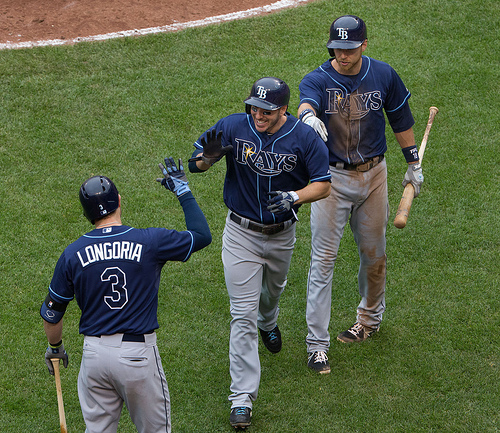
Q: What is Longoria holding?
A: Bat.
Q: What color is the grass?
A: Green.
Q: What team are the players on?
A: Rays.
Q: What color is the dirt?
A: Brown.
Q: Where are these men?
A: On field.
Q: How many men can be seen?
A: 3.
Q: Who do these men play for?
A: Rays.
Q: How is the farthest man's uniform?
A: Dirty.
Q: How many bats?
A: 2.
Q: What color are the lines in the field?
A: White.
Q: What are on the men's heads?
A: Helmets.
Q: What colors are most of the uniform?
A: Grays and blue.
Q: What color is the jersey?
A: Blue.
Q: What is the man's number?
A: 3.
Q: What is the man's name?
A: Longoria.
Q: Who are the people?
A: Men.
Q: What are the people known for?
A: Baseball.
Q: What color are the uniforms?
A: Blue.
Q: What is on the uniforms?
A: Dirt.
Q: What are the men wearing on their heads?
A: Helmets.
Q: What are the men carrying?
A: Bats.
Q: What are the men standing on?
A: Grass.